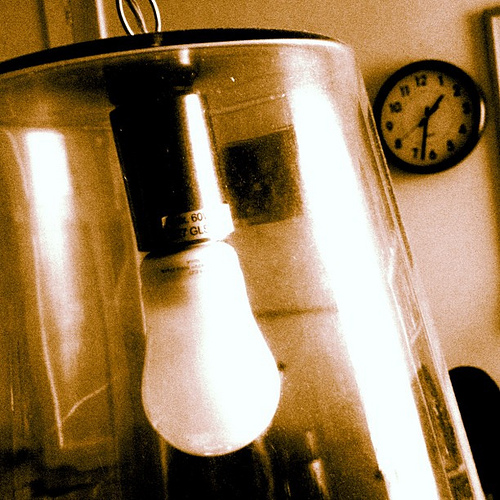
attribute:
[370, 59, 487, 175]
clock — round, black, white, glaring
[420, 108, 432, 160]
minute hand — black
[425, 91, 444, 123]
hour hand — black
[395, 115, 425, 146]
second hand — skinny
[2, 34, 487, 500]
container — glass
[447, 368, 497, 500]
object — black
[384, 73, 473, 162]
numbers — black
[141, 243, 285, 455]
light bulb — white, glaring, upside down, shiny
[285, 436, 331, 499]
vase — metal